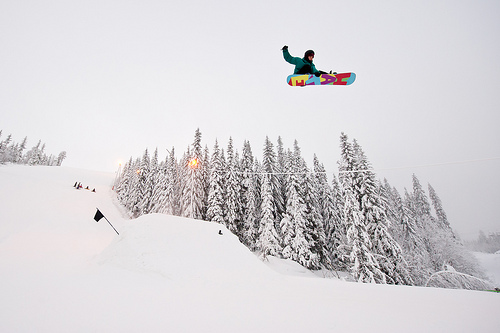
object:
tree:
[207, 134, 226, 225]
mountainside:
[0, 162, 500, 331]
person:
[281, 44, 339, 76]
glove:
[280, 45, 292, 51]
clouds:
[0, 0, 500, 164]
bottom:
[286, 72, 358, 87]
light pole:
[182, 155, 203, 218]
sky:
[0, 0, 500, 167]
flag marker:
[90, 207, 124, 236]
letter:
[333, 72, 351, 85]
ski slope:
[0, 160, 500, 332]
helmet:
[303, 49, 315, 58]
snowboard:
[284, 72, 358, 87]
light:
[189, 157, 201, 217]